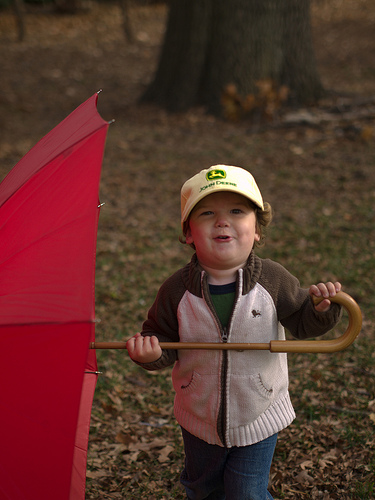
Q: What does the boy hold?
A: Umbrella.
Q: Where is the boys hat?
A: Head.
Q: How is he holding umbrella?
A: Handle.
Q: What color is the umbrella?
A: Red.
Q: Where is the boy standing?
A: Grass.